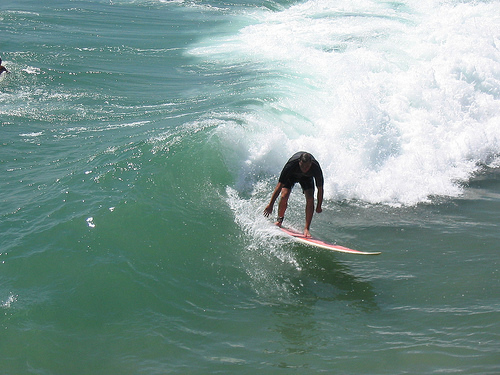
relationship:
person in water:
[0, 59, 7, 76] [2, 3, 499, 374]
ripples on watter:
[15, 30, 111, 109] [5, 6, 275, 366]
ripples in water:
[336, 262, 424, 292] [2, 3, 499, 374]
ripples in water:
[367, 296, 497, 368] [2, 3, 499, 374]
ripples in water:
[4, 120, 195, 311] [2, 3, 499, 374]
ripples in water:
[342, 306, 410, 356] [126, 180, 431, 337]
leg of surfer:
[275, 190, 292, 220] [197, 111, 410, 337]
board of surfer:
[272, 220, 382, 255] [263, 150, 323, 238]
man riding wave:
[261, 151, 326, 239] [169, 111, 264, 186]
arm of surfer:
[314, 166, 328, 218] [259, 143, 386, 268]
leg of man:
[298, 185, 318, 235] [261, 151, 326, 239]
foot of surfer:
[275, 221, 283, 227] [263, 150, 323, 238]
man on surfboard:
[261, 149, 325, 237] [267, 220, 382, 260]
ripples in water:
[79, 92, 143, 140] [61, 282, 312, 344]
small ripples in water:
[201, 306, 346, 366] [2, 3, 499, 374]